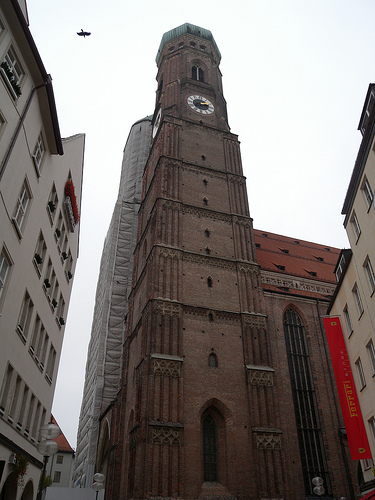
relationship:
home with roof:
[254, 225, 335, 279] [260, 229, 335, 286]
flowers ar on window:
[59, 174, 89, 228] [57, 172, 87, 237]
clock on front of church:
[185, 89, 217, 121] [108, 12, 300, 498]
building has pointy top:
[0, 122, 90, 490] [63, 121, 96, 173]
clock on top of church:
[185, 89, 217, 121] [108, 12, 300, 498]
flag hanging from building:
[313, 304, 374, 468] [319, 81, 374, 500]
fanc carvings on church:
[189, 381, 240, 495] [108, 12, 339, 498]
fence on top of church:
[148, 34, 228, 67] [108, 12, 339, 498]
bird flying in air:
[70, 23, 99, 48] [32, 6, 161, 118]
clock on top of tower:
[185, 89, 217, 121] [134, 12, 261, 297]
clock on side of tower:
[148, 103, 163, 137] [134, 12, 261, 297]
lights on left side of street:
[90, 464, 109, 497] [10, 443, 95, 497]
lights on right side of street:
[304, 469, 333, 499] [298, 455, 365, 496]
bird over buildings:
[70, 23, 99, 48] [2, 23, 75, 487]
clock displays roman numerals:
[185, 89, 217, 121] [183, 90, 219, 122]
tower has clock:
[134, 12, 261, 297] [185, 89, 217, 121]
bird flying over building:
[70, 23, 99, 48] [0, 122, 90, 490]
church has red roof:
[108, 12, 300, 498] [254, 225, 335, 279]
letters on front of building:
[313, 304, 374, 468] [319, 81, 374, 500]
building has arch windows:
[108, 12, 339, 498] [192, 280, 328, 499]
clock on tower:
[185, 89, 217, 121] [134, 12, 261, 297]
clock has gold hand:
[185, 89, 217, 121] [198, 99, 212, 109]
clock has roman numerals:
[185, 89, 217, 121] [183, 90, 219, 122]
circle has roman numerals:
[185, 89, 217, 121] [183, 90, 219, 122]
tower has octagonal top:
[134, 12, 261, 297] [148, 17, 228, 78]